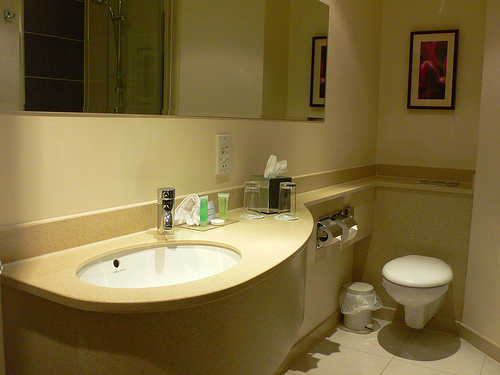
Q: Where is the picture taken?
A: In a bathroom.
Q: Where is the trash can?
A: In the corner.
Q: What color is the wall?
A: Tan.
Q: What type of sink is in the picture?
A: Undermount.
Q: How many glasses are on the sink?
A: Two.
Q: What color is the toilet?
A: White.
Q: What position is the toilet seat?
A: Down.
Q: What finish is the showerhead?
A: Chrome.